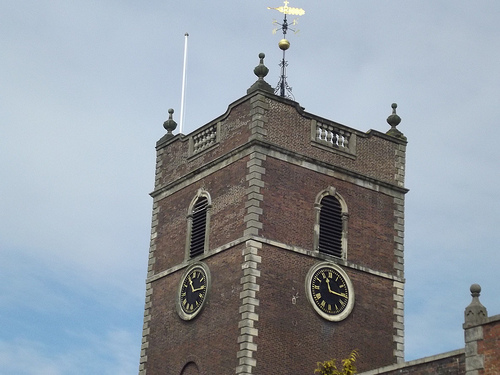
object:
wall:
[246, 88, 406, 374]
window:
[313, 186, 349, 262]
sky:
[0, 0, 500, 375]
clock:
[302, 260, 356, 323]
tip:
[265, 0, 305, 57]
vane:
[267, 0, 307, 102]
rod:
[180, 31, 190, 133]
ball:
[277, 38, 291, 51]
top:
[155, 53, 407, 190]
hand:
[188, 275, 196, 293]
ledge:
[188, 119, 220, 158]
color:
[210, 132, 303, 199]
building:
[134, 51, 410, 375]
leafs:
[349, 357, 355, 362]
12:
[192, 272, 196, 279]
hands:
[192, 287, 205, 293]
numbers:
[314, 285, 321, 290]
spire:
[384, 102, 407, 139]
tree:
[312, 347, 360, 374]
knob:
[463, 281, 489, 323]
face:
[179, 266, 208, 316]